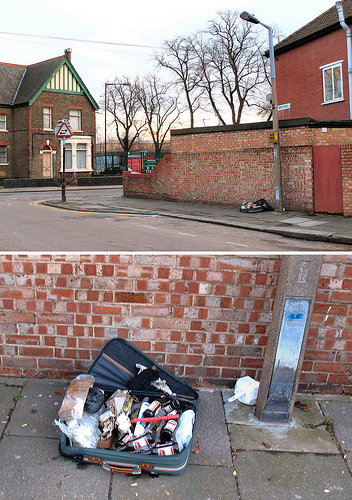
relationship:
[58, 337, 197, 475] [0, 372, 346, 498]
luggage on ground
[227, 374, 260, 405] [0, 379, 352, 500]
bag on ground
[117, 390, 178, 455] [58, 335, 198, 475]
bottles in luggage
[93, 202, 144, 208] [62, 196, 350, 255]
leaves on sidewalk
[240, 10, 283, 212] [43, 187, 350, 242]
post on sidewalk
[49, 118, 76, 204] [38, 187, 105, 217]
street sign on corner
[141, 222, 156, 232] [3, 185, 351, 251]
line on ground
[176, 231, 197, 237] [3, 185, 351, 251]
line on ground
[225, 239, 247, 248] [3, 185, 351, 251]
line on ground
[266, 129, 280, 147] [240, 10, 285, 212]
sign on post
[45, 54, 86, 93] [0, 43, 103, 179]
trim on house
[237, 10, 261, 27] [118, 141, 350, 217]
lamp next to wall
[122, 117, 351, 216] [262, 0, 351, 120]
wall next to house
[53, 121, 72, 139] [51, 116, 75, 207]
sign on pole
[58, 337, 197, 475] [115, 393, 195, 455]
luggage with bottles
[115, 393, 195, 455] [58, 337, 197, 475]
bottles in luggage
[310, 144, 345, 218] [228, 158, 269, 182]
gate on brick wall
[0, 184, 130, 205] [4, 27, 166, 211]
street in between houses